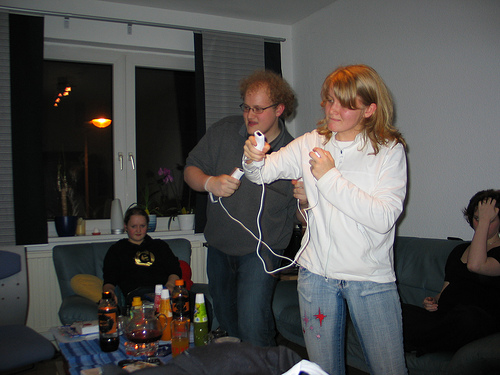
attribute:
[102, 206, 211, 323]
woman — sitting, watching, starring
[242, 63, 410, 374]
person — standing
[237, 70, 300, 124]
hair — curly, blonde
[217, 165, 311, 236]
wii controller — white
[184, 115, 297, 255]
shirt — gray, short sleeved.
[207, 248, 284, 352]
jeans — blue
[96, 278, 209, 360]
drinks — all types, alcoholic., on table, in abundance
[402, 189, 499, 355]
girl — sitting down, sitting, combing hair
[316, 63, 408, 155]
hair — long., blonde.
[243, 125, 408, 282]
jacket — long sleeved., white, worn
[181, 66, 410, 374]
people — playing games, playing, standing, playing the wii., drinking, playing video games, using wii console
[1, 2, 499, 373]
party — a game party, indoors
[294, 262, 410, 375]
jeans — blue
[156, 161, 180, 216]
flowers — purple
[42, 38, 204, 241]
window — on house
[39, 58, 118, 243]
window — dark